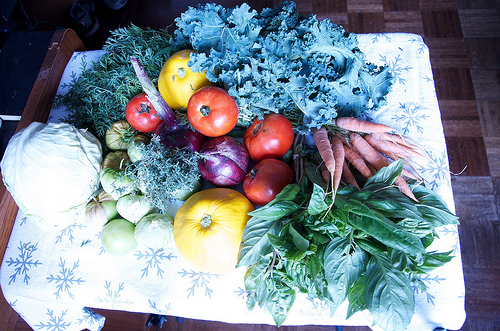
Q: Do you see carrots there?
A: Yes, there is a carrot.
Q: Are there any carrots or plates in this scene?
A: Yes, there is a carrot.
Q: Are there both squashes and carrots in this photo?
A: Yes, there are both a carrot and a squash.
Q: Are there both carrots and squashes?
A: Yes, there are both a carrot and a squash.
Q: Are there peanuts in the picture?
A: No, there are no peanuts.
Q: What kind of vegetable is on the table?
A: The vegetable is a carrot.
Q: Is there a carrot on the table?
A: Yes, there is a carrot on the table.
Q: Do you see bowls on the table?
A: No, there is a carrot on the table.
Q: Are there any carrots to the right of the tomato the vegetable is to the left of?
A: Yes, there is a carrot to the right of the tomato.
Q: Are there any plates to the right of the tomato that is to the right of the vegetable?
A: No, there is a carrot to the right of the tomato.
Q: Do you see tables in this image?
A: Yes, there is a table.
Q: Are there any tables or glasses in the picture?
A: Yes, there is a table.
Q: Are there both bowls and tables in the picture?
A: No, there is a table but no bowls.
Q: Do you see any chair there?
A: No, there are no chairs.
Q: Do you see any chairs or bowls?
A: No, there are no chairs or bowls.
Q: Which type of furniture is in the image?
A: The furniture is a table.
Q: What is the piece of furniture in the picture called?
A: The piece of furniture is a table.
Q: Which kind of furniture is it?
A: The piece of furniture is a table.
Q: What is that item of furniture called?
A: This is a table.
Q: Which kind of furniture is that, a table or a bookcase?
A: This is a table.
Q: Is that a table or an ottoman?
A: That is a table.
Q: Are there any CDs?
A: No, there are no cds.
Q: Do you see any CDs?
A: No, there are no cds.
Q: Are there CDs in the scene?
A: No, there are no cds.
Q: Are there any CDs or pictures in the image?
A: No, there are no CDs or pictures.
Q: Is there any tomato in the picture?
A: Yes, there is a tomato.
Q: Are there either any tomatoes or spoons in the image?
A: Yes, there is a tomato.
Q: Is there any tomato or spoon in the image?
A: Yes, there is a tomato.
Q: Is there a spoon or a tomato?
A: Yes, there is a tomato.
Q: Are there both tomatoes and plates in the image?
A: No, there is a tomato but no plates.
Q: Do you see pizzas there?
A: No, there are no pizzas.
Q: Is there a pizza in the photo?
A: No, there are no pizzas.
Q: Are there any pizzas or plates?
A: No, there are no pizzas or plates.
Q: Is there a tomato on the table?
A: Yes, there is a tomato on the table.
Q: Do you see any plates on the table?
A: No, there is a tomato on the table.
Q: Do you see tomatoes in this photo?
A: Yes, there is a tomato.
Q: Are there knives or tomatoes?
A: Yes, there is a tomato.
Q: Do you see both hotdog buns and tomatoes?
A: No, there is a tomato but no hotdog buns.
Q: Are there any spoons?
A: No, there are no spoons.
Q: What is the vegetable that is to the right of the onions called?
A: The vegetable is a tomato.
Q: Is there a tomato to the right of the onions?
A: Yes, there is a tomato to the right of the onions.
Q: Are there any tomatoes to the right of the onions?
A: Yes, there is a tomato to the right of the onions.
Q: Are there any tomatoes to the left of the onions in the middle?
A: No, the tomato is to the right of the onions.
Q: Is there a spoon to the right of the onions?
A: No, there is a tomato to the right of the onions.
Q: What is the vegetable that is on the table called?
A: The vegetable is a tomato.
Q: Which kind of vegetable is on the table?
A: The vegetable is a tomato.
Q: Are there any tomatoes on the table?
A: Yes, there is a tomato on the table.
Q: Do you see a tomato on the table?
A: Yes, there is a tomato on the table.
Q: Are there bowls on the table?
A: No, there is a tomato on the table.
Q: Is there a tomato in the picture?
A: Yes, there is a tomato.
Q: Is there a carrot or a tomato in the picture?
A: Yes, there is a tomato.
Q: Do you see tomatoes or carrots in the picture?
A: Yes, there is a tomato.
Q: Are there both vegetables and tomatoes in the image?
A: Yes, there are both a tomato and vegetables.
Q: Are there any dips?
A: No, there are no dips.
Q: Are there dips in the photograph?
A: No, there are no dips.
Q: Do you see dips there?
A: No, there are no dips.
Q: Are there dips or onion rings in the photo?
A: No, there are no dips or onion rings.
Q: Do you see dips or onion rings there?
A: No, there are no dips or onion rings.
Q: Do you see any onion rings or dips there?
A: No, there are no dips or onion rings.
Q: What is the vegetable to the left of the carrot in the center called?
A: The vegetable is a tomato.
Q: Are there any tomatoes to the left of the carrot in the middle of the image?
A: Yes, there is a tomato to the left of the carrot.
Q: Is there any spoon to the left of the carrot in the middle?
A: No, there is a tomato to the left of the carrot.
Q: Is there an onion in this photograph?
A: Yes, there are onions.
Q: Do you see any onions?
A: Yes, there are onions.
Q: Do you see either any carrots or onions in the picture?
A: Yes, there are onions.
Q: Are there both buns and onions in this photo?
A: No, there are onions but no buns.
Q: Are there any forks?
A: No, there are no forks.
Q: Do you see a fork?
A: No, there are no forks.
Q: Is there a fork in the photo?
A: No, there are no forks.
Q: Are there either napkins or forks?
A: No, there are no forks or napkins.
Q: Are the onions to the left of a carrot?
A: Yes, the onions are to the left of a carrot.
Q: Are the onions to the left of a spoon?
A: No, the onions are to the left of a carrot.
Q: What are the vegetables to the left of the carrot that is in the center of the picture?
A: The vegetables are onions.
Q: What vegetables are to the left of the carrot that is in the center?
A: The vegetables are onions.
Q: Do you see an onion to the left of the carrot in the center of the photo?
A: Yes, there are onions to the left of the carrot.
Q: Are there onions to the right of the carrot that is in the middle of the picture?
A: No, the onions are to the left of the carrot.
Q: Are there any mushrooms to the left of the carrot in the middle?
A: No, there are onions to the left of the carrot.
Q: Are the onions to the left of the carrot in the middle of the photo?
A: Yes, the onions are to the left of the carrot.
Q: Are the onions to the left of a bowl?
A: No, the onions are to the left of a tomato.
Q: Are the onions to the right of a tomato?
A: No, the onions are to the left of a tomato.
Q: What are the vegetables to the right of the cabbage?
A: The vegetables are onions.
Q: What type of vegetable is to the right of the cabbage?
A: The vegetables are onions.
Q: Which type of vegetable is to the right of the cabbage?
A: The vegetables are onions.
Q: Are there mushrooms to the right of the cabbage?
A: No, there are onions to the right of the cabbage.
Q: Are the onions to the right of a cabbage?
A: Yes, the onions are to the right of a cabbage.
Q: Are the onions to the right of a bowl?
A: No, the onions are to the right of a cabbage.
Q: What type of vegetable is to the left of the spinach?
A: The vegetables are onions.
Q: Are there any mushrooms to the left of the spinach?
A: No, there are onions to the left of the spinach.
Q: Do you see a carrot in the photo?
A: Yes, there are carrots.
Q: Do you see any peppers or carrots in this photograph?
A: Yes, there are carrots.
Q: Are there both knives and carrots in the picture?
A: No, there are carrots but no knives.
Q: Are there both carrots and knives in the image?
A: No, there are carrots but no knives.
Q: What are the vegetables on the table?
A: The vegetables are carrots.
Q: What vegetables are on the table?
A: The vegetables are carrots.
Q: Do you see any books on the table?
A: No, there are carrots on the table.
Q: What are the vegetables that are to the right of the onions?
A: The vegetables are carrots.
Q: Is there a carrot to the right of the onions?
A: Yes, there are carrots to the right of the onions.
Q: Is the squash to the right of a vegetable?
A: Yes, the squash is to the right of a vegetable.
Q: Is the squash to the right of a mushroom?
A: No, the squash is to the right of a vegetable.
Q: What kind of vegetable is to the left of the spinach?
A: The vegetable is a squash.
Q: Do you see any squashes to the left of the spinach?
A: Yes, there is a squash to the left of the spinach.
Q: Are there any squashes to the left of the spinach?
A: Yes, there is a squash to the left of the spinach.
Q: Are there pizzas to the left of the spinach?
A: No, there is a squash to the left of the spinach.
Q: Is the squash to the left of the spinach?
A: Yes, the squash is to the left of the spinach.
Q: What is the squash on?
A: The squash is on the table.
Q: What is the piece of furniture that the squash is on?
A: The piece of furniture is a table.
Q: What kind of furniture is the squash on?
A: The squash is on the table.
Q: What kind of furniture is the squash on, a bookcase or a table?
A: The squash is on a table.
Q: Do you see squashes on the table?
A: Yes, there is a squash on the table.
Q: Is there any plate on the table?
A: No, there is a squash on the table.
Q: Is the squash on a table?
A: Yes, the squash is on a table.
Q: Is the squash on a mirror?
A: No, the squash is on a table.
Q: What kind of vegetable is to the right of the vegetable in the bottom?
A: The vegetable is a squash.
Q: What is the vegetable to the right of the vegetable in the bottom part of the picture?
A: The vegetable is a squash.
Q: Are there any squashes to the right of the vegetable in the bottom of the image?
A: Yes, there is a squash to the right of the vegetable.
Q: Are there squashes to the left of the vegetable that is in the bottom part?
A: No, the squash is to the right of the vegetable.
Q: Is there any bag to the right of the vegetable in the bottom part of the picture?
A: No, there is a squash to the right of the vegetable.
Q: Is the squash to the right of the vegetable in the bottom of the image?
A: Yes, the squash is to the right of the vegetable.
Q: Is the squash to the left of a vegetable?
A: No, the squash is to the right of a vegetable.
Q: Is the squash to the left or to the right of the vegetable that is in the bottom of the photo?
A: The squash is to the right of the vegetable.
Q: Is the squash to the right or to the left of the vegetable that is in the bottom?
A: The squash is to the right of the vegetable.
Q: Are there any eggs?
A: No, there are no eggs.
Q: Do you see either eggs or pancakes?
A: No, there are no eggs or pancakes.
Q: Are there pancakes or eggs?
A: No, there are no eggs or pancakes.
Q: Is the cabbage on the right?
A: No, the cabbage is on the left of the image.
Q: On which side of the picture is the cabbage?
A: The cabbage is on the left of the image.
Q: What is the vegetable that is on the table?
A: The vegetable is a cabbage.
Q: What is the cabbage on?
A: The cabbage is on the table.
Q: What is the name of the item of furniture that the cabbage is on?
A: The piece of furniture is a table.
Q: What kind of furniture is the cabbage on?
A: The cabbage is on the table.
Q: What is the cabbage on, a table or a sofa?
A: The cabbage is on a table.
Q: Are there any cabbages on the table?
A: Yes, there is a cabbage on the table.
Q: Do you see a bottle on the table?
A: No, there is a cabbage on the table.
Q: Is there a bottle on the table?
A: No, there is a cabbage on the table.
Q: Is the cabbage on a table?
A: Yes, the cabbage is on a table.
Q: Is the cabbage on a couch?
A: No, the cabbage is on a table.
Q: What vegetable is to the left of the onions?
A: The vegetable is a cabbage.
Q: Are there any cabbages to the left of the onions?
A: Yes, there is a cabbage to the left of the onions.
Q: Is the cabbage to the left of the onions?
A: Yes, the cabbage is to the left of the onions.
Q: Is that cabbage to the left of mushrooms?
A: No, the cabbage is to the left of the onions.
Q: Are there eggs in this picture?
A: No, there are no eggs.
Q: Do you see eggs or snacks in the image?
A: No, there are no eggs or snacks.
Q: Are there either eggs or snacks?
A: No, there are no eggs or snacks.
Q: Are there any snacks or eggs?
A: No, there are no eggs or snacks.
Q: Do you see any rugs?
A: No, there are no rugs.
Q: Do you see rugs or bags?
A: No, there are no rugs or bags.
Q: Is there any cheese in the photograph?
A: No, there is no cheese.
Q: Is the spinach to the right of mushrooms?
A: No, the spinach is to the right of the onions.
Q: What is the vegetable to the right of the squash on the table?
A: The vegetable is spinach.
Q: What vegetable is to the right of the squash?
A: The vegetable is spinach.